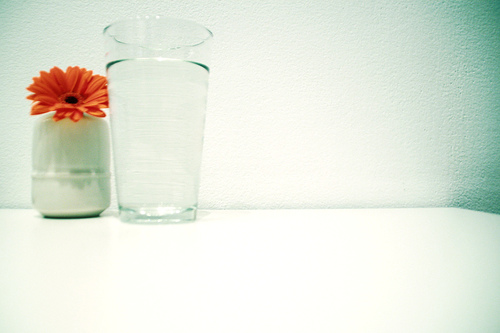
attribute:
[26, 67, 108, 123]
flower — orange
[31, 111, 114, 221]
vase — white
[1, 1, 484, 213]
wall — white, bright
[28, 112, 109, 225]
vase — short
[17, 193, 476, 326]
table — white, clean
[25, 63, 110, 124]
flower — red, vibrant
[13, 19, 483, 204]
walls — white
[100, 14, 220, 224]
glass — clear, almost-full, big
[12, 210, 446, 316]
table — white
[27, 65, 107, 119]
flower — orange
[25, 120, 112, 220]
vase — flower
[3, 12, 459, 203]
wall — white, textured, bright